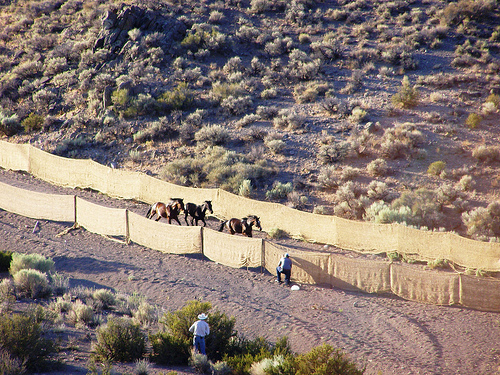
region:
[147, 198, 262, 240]
Several horses walking around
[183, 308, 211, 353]
Person behind the bush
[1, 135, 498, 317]
Borders surrounding the horses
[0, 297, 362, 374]
Several bushes on the side of the border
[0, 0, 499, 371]
Desolated area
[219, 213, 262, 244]
Brown horse leading the pack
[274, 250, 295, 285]
Person kneeling close to the border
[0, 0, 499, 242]
Several bushes around the area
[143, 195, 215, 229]
Horses behind the pack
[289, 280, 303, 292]
White hat on the ground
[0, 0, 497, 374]
capturing wild horses in semi-arid land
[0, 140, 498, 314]
cloth chute to funnel horses into corral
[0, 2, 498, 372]
semi-arid landscape with sagebrush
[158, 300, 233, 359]
cowboy hiding behind vegetation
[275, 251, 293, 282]
man hiding behind cloth fence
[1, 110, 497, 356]
wild horse roundup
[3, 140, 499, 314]
wild horses following cloth fencing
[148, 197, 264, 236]
wild horses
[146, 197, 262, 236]
four horses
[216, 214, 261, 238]
wild horse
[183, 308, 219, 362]
a man in a white hat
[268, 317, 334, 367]
the trees are beside the road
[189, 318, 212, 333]
the t shirt is white in color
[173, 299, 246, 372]
man is trimming the plants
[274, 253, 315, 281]
man is making the fence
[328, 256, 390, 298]
the fence cloth is grey in color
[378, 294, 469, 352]
the floor is grey in color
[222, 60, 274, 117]
bunches of shrubs at the fopre of the road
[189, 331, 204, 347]
the pants are blue in color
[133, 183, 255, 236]
horses are running on the way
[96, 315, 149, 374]
Green bush in a dessert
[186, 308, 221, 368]
Cowboy standing in bushes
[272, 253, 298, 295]
Man kneeling in dirt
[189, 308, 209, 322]
White cowboy hat on a man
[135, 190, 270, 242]
Three horses running in a track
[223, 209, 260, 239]
Brown horse running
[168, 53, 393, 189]
Bushes in the dessert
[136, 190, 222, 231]
Two horses running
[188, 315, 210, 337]
Shirt on a man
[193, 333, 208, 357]
Blue jeans on a man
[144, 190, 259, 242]
three horses running in an enclosure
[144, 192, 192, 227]
glossy brown horse running in an enclosure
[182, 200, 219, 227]
dark brown horse running in an enclosure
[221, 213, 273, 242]
brown horse running in an enclosure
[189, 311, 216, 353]
man standing behind a bush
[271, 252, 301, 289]
man working on a burlap fence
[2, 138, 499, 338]
cloth fence around path for horses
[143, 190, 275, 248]
horses running on a path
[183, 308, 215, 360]
man wearing a cowboy hat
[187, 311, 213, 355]
man lurking behind a bush